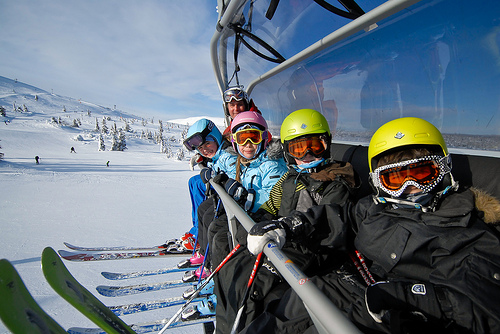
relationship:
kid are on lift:
[273, 116, 500, 333] [27, 3, 429, 332]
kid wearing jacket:
[273, 116, 500, 333] [371, 214, 484, 304]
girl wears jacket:
[188, 111, 290, 279] [231, 165, 279, 197]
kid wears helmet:
[222, 107, 360, 334] [278, 99, 337, 149]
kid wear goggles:
[273, 116, 500, 333] [193, 126, 470, 196]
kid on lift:
[273, 116, 500, 333] [206, 0, 499, 334]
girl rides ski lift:
[180, 117, 236, 252] [159, 0, 496, 332]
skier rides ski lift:
[218, 80, 268, 125] [159, 0, 496, 332]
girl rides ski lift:
[188, 111, 290, 279] [159, 0, 496, 332]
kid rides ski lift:
[222, 107, 360, 334] [159, 0, 496, 332]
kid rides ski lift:
[273, 116, 500, 333] [159, 0, 496, 332]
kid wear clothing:
[273, 116, 500, 333] [204, 152, 498, 322]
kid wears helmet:
[250, 116, 495, 324] [347, 100, 464, 196]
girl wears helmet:
[209, 109, 290, 274] [220, 104, 265, 134]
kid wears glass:
[273, 116, 500, 333] [369, 153, 453, 197]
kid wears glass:
[244, 107, 360, 331] [284, 133, 332, 161]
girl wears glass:
[188, 111, 290, 279] [232, 128, 267, 146]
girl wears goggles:
[180, 117, 236, 252] [177, 129, 209, 153]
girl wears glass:
[184, 117, 226, 277] [182, 132, 206, 151]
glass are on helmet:
[182, 132, 206, 151] [182, 117, 222, 157]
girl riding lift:
[180, 117, 236, 252] [206, 0, 499, 334]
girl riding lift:
[188, 111, 290, 279] [206, 0, 499, 334]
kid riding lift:
[222, 107, 360, 334] [206, 0, 499, 334]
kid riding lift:
[273, 116, 500, 333] [206, 0, 499, 334]